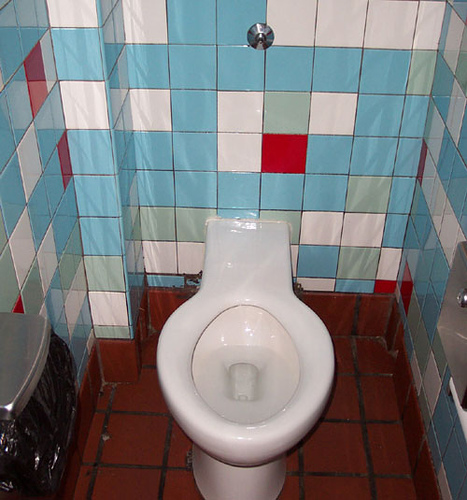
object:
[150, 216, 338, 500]
toilet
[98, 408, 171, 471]
tiles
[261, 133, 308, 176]
tile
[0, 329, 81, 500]
bag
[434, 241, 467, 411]
container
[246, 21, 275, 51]
button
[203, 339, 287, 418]
water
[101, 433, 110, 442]
litter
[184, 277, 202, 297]
residue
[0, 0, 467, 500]
wall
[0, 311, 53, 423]
can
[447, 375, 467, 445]
paper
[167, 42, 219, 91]
tile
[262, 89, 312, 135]
tile